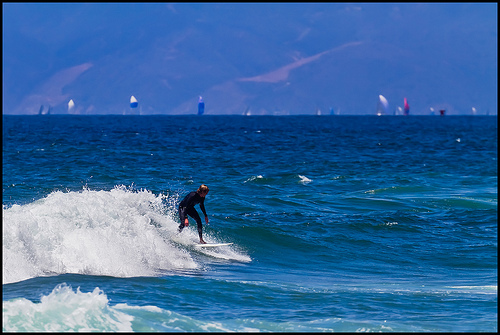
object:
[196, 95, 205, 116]
boats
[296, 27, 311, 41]
white clouds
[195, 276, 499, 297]
line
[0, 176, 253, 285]
wave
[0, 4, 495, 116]
sky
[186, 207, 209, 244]
legs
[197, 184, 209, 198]
head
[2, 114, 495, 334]
blue ocean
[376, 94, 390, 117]
sailboat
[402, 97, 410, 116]
sailboat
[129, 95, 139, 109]
sailboat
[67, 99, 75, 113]
sailboat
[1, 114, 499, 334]
ocean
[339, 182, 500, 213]
curves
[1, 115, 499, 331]
water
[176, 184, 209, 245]
man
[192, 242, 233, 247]
surfboard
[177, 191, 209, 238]
wet suit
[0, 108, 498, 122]
horizon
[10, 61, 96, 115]
cloud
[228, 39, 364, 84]
cloud